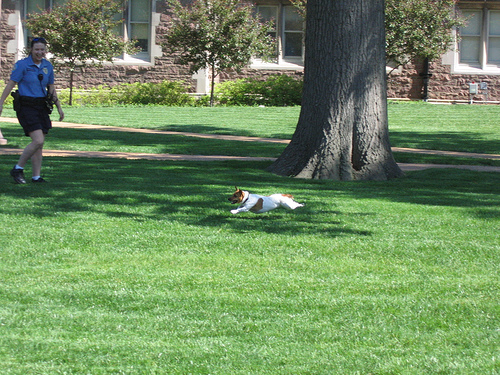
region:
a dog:
[220, 178, 309, 224]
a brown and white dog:
[221, 181, 315, 227]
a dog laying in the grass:
[221, 173, 312, 225]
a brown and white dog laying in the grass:
[219, 184, 321, 219]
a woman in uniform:
[1, 24, 69, 189]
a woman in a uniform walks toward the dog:
[4, 28, 76, 196]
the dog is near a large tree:
[215, 6, 407, 251]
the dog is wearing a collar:
[214, 168, 313, 222]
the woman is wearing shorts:
[2, 28, 84, 186]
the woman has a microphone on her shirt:
[5, 28, 72, 191]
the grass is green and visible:
[144, 218, 244, 313]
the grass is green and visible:
[66, 178, 175, 271]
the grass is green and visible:
[109, 146, 271, 370]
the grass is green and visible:
[124, 206, 231, 356]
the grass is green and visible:
[114, 244, 195, 370]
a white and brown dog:
[219, 183, 304, 220]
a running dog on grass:
[224, 186, 302, 218]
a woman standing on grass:
[6, 33, 67, 185]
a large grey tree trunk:
[271, 4, 396, 180]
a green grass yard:
[2, 153, 495, 373]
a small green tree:
[159, 3, 275, 97]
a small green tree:
[382, 0, 465, 97]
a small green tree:
[23, 3, 127, 101]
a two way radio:
[36, 69, 53, 97]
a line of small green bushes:
[127, 75, 298, 106]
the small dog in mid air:
[227, 182, 300, 217]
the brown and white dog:
[226, 183, 304, 215]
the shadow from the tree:
[75, 150, 395, 255]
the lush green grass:
[155, 248, 498, 365]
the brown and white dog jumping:
[225, 182, 311, 218]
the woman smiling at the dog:
[5, 32, 65, 189]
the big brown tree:
[263, 4, 408, 179]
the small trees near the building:
[33, 2, 433, 124]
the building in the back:
[10, 0, 290, 102]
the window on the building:
[112, 2, 169, 67]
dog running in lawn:
[223, 175, 315, 234]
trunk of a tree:
[266, 2, 414, 186]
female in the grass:
[2, 31, 68, 195]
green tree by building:
[146, 1, 271, 112]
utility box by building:
[466, 75, 479, 105]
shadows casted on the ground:
[90, 155, 210, 206]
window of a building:
[127, 1, 159, 46]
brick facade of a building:
[88, 62, 190, 81]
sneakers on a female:
[12, 165, 61, 190]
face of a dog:
[226, 182, 248, 205]